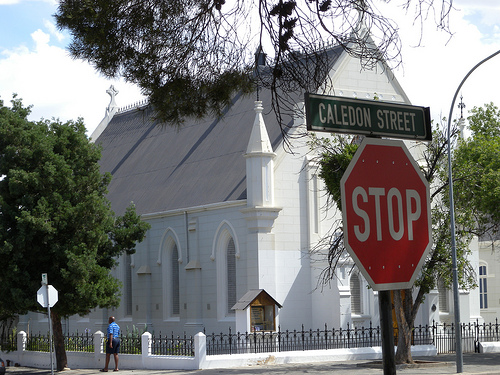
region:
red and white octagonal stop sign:
[330, 137, 447, 297]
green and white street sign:
[302, 83, 436, 140]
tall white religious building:
[82, 21, 479, 352]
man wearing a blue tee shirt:
[97, 308, 124, 374]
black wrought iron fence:
[4, 300, 496, 370]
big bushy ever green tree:
[2, 90, 148, 372]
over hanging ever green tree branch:
[50, 0, 462, 138]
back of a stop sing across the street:
[32, 280, 65, 313]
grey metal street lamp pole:
[443, 43, 495, 374]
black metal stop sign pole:
[372, 286, 402, 372]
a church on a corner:
[19, 24, 476, 361]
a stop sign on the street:
[289, 84, 464, 363]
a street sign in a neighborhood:
[283, 79, 459, 149]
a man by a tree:
[6, 96, 143, 373]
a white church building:
[99, 112, 375, 374]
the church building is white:
[308, 201, 499, 343]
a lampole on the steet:
[426, 39, 485, 374]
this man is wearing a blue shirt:
[95, 317, 138, 367]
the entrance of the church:
[313, 232, 440, 359]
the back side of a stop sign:
[24, 262, 72, 374]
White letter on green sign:
[313, 94, 330, 132]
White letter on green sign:
[322, 100, 331, 132]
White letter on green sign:
[328, 98, 343, 133]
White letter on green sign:
[336, 102, 352, 127]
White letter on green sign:
[347, 103, 357, 132]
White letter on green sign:
[353, 102, 364, 137]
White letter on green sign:
[360, 98, 375, 133]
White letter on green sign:
[376, 104, 389, 136]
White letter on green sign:
[390, 105, 400, 139]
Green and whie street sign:
[287, 68, 454, 150]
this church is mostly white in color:
[73, 19, 443, 349]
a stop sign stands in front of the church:
[336, 132, 437, 292]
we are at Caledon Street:
[300, 87, 435, 148]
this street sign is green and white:
[298, 87, 438, 142]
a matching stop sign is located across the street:
[32, 269, 67, 371]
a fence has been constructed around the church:
[1, 319, 497, 369]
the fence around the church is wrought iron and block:
[3, 319, 499, 368]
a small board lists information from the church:
[231, 284, 286, 353]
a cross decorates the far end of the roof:
[101, 79, 121, 114]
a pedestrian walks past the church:
[99, 313, 125, 374]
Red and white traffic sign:
[325, 129, 447, 359]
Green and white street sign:
[283, 73, 462, 157]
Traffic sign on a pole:
[26, 273, 66, 308]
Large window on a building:
[207, 221, 257, 323]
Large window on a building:
[153, 232, 189, 322]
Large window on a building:
[103, 236, 145, 322]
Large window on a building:
[337, 261, 364, 330]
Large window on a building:
[476, 255, 493, 315]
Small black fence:
[188, 325, 421, 346]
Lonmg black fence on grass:
[13, 328, 213, 363]